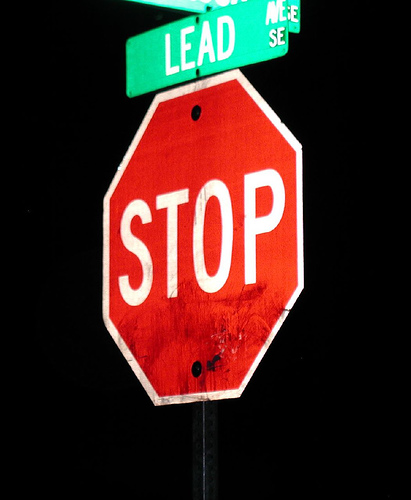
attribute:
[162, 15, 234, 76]
letters — white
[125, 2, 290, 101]
street sign — here, green, reflective, shiny, dirty, legible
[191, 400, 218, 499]
post — metal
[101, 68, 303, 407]
stop sign — spotted, dirty, red, here, white trimmed, marked up, octagonal, rippled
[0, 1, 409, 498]
sky — dark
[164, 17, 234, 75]
lead — printed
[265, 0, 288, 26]
ave — printed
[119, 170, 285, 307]
stop — printed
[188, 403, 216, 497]
pole — here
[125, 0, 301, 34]
street sign — partially shown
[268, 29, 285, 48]
se — printed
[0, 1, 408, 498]
background — black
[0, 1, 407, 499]
photo — nighttime